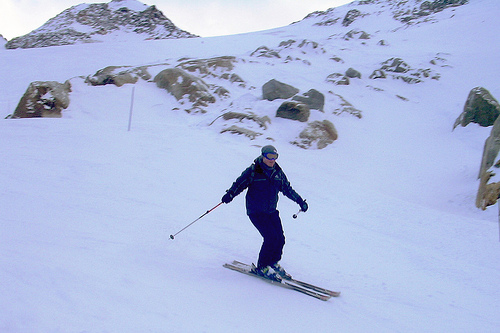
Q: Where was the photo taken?
A: On a ski slope.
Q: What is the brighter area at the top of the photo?
A: The sky.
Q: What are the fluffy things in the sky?
A: Clouds.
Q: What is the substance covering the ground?
A: Snow.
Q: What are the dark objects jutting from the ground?
A: Rocks.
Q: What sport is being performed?
A: Skiing.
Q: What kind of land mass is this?
A: A mountain.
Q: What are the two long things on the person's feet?
A: Skis.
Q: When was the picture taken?
A: During day hours.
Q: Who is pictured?
A: Skier.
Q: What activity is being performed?
A: Skiing.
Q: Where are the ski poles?
A: Person's hands.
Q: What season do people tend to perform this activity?
A: Winter.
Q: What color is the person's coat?
A: Blue.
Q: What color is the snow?
A: White.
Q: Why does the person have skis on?
A: Skiing.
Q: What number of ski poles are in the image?
A: Two.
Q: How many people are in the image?
A: One.